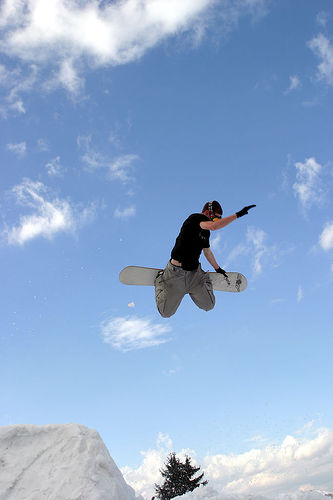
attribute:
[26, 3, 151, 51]
clouds — white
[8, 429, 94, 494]
snow — white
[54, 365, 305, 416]
sky — blue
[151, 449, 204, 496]
tree — green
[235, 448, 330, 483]
clouds — white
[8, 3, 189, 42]
clouds — white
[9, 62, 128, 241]
clouds — white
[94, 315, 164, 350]
clouds — white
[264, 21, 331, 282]
clouds — white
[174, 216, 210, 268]
shirt — black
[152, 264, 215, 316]
pants — grey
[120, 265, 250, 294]
snowboard — white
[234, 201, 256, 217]
gloves — black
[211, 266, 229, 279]
gloves — black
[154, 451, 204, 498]
tree — tall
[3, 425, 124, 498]
snow — white, mounds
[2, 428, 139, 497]
snow — mounds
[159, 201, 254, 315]
person — snowboarding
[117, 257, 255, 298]
snowboard — grey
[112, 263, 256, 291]
snowboard — grey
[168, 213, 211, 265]
shirt — black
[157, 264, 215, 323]
pants — grey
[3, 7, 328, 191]
sky — blue, cloudy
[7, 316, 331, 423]
sky — blue, cloudy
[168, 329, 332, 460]
sky — blue, cloudy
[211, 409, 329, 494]
sky — blue, cloudy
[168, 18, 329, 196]
sky — blue, cloudy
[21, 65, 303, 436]
sky — Blue 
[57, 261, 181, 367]
clouds — white 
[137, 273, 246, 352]
pants — Grey 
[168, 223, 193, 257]
shirt — Black 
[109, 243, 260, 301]
snowboard — white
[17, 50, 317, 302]
sky — blue, cloudy